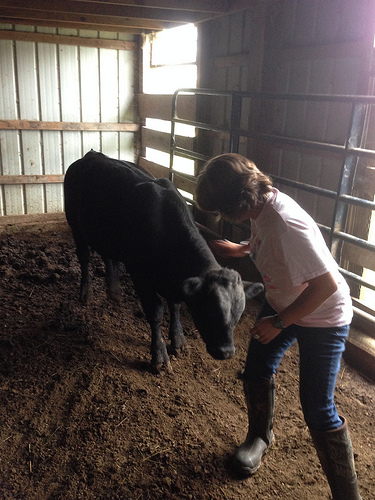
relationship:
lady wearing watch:
[193, 154, 359, 500] [267, 312, 288, 331]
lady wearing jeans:
[193, 154, 359, 500] [243, 298, 349, 434]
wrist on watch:
[264, 308, 306, 335] [267, 311, 288, 331]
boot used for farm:
[218, 359, 284, 489] [4, 287, 373, 495]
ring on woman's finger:
[256, 332, 263, 338] [252, 330, 265, 341]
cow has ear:
[58, 146, 264, 375] [176, 269, 207, 304]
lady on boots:
[193, 154, 359, 500] [234, 412, 348, 487]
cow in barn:
[58, 146, 264, 375] [31, 56, 372, 481]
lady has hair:
[147, 84, 373, 494] [201, 151, 274, 216]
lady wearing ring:
[147, 84, 373, 494] [254, 334, 260, 340]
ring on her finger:
[254, 334, 260, 340] [242, 322, 263, 361]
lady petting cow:
[193, 154, 359, 500] [58, 146, 264, 375]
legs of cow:
[119, 296, 196, 389] [51, 145, 255, 394]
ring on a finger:
[254, 334, 260, 340] [246, 330, 269, 342]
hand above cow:
[210, 237, 245, 256] [58, 146, 264, 375]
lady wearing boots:
[193, 154, 359, 500] [240, 368, 282, 478]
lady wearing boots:
[193, 154, 359, 500] [317, 419, 364, 496]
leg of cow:
[147, 288, 174, 371] [58, 146, 264, 375]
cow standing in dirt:
[58, 146, 264, 375] [90, 315, 131, 340]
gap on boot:
[243, 424, 265, 444] [229, 372, 276, 474]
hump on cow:
[138, 169, 172, 201] [58, 146, 264, 375]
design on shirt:
[228, 236, 301, 313] [245, 227, 293, 306]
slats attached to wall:
[0, 29, 143, 225] [4, 20, 145, 225]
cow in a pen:
[62, 147, 264, 377] [9, 87, 373, 383]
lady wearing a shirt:
[193, 154, 359, 500] [236, 205, 365, 353]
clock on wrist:
[272, 312, 285, 329] [270, 312, 287, 334]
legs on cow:
[72, 228, 123, 303] [58, 146, 264, 375]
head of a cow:
[180, 265, 265, 359] [58, 146, 264, 375]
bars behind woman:
[239, 65, 325, 168] [191, 147, 373, 499]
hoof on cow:
[151, 356, 178, 377] [58, 146, 264, 375]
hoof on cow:
[172, 328, 188, 348] [58, 146, 264, 375]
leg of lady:
[244, 307, 292, 439] [193, 154, 359, 500]